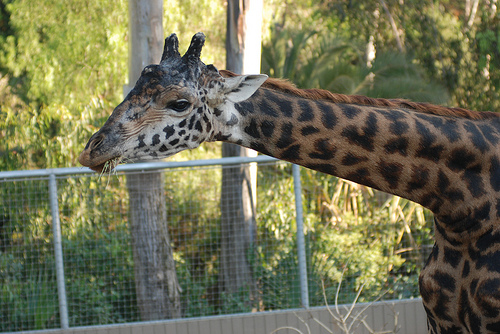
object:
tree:
[122, 0, 269, 318]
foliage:
[309, 37, 442, 99]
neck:
[241, 68, 438, 203]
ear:
[222, 72, 272, 103]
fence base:
[1, 298, 426, 332]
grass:
[0, 155, 283, 334]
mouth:
[76, 151, 131, 172]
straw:
[90, 158, 135, 188]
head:
[77, 32, 220, 177]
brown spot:
[165, 133, 182, 149]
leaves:
[0, 0, 130, 105]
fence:
[1, 154, 439, 333]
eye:
[167, 98, 193, 112]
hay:
[95, 155, 137, 187]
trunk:
[82, 31, 223, 170]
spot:
[339, 111, 378, 153]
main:
[219, 69, 499, 121]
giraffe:
[75, 32, 499, 334]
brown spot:
[250, 90, 498, 332]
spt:
[176, 117, 188, 127]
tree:
[264, 8, 457, 165]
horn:
[161, 30, 181, 60]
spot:
[317, 104, 339, 130]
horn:
[182, 32, 205, 60]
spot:
[177, 117, 191, 134]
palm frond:
[256, 27, 452, 104]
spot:
[308, 136, 339, 160]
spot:
[296, 99, 316, 122]